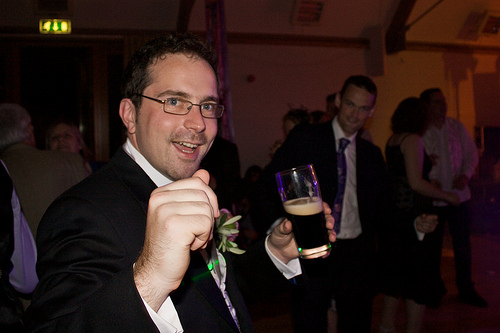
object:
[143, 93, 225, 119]
eyeglasses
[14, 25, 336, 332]
man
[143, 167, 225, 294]
hand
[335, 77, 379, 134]
head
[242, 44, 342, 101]
wall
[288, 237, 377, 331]
pants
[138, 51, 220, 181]
face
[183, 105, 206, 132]
nose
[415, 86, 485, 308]
man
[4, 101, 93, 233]
man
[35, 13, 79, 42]
sign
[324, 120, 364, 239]
shirt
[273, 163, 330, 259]
glass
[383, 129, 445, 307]
black dress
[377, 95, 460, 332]
lady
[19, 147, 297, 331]
blazer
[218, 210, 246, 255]
carnation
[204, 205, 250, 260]
corsage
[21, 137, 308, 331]
suit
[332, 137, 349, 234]
tie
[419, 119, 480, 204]
white shirt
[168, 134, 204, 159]
mouth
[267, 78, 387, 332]
man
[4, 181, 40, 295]
white shirt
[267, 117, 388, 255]
blazer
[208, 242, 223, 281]
tie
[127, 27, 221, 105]
hair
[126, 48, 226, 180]
head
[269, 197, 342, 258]
hand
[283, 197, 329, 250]
beer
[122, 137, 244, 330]
shirt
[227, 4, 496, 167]
background